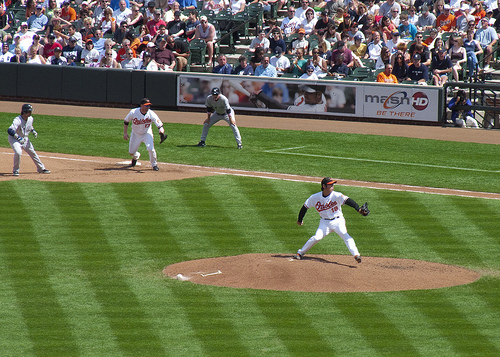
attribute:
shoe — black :
[150, 160, 161, 172]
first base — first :
[0, 142, 197, 187]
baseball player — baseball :
[292, 173, 369, 264]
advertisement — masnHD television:
[174, 74, 439, 125]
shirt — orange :
[379, 72, 397, 85]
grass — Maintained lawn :
[0, 110, 498, 353]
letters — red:
[132, 117, 151, 128]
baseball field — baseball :
[0, 98, 497, 355]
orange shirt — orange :
[378, 70, 398, 82]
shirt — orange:
[367, 55, 400, 87]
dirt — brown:
[162, 251, 479, 293]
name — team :
[314, 195, 346, 216]